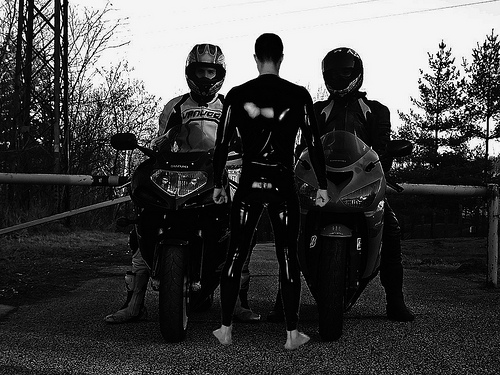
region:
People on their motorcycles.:
[111, 42, 413, 339]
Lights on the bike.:
[113, 119, 222, 216]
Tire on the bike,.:
[88, 237, 250, 342]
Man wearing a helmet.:
[276, 31, 382, 130]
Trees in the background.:
[21, 19, 158, 196]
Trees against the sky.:
[373, 19, 498, 193]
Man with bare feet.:
[201, 272, 283, 368]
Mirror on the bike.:
[108, 119, 165, 161]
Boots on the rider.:
[63, 239, 177, 344]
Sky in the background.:
[80, 13, 213, 129]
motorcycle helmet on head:
[183, 43, 228, 100]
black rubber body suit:
[214, 77, 316, 329]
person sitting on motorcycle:
[298, 49, 416, 329]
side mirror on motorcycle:
[107, 130, 152, 162]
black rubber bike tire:
[314, 240, 348, 341]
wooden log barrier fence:
[1, 172, 499, 284]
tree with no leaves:
[64, 4, 154, 181]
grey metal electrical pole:
[14, 1, 70, 226]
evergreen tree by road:
[398, 41, 478, 186]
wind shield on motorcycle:
[313, 133, 368, 163]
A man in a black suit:
[210, 30, 332, 350]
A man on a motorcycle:
[288, 45, 413, 329]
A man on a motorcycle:
[100, 40, 242, 327]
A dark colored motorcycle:
[295, 130, 387, 342]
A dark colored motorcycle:
[104, 133, 245, 345]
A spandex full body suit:
[211, 73, 328, 330]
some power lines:
[0, 0, 495, 70]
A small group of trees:
[4, 4, 162, 198]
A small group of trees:
[386, 24, 498, 187]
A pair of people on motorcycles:
[97, 44, 414, 326]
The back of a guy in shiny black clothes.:
[211, 32, 328, 351]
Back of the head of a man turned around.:
[253, 33, 285, 77]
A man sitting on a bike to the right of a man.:
[268, 45, 413, 323]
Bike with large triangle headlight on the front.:
[109, 132, 243, 344]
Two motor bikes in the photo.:
[109, 132, 414, 342]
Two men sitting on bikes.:
[105, 43, 417, 325]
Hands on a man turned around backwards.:
[210, 184, 330, 206]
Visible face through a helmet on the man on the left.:
[191, 65, 216, 80]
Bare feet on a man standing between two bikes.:
[211, 323, 311, 351]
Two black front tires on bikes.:
[157, 229, 349, 343]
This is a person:
[121, 23, 221, 348]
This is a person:
[221, 17, 310, 372]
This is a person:
[307, 19, 425, 368]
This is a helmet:
[178, 28, 244, 123]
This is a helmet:
[316, 31, 383, 108]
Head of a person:
[174, 28, 231, 104]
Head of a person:
[244, 14, 306, 99]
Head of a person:
[314, 33, 377, 138]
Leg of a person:
[274, 200, 316, 370]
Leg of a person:
[211, 205, 259, 373]